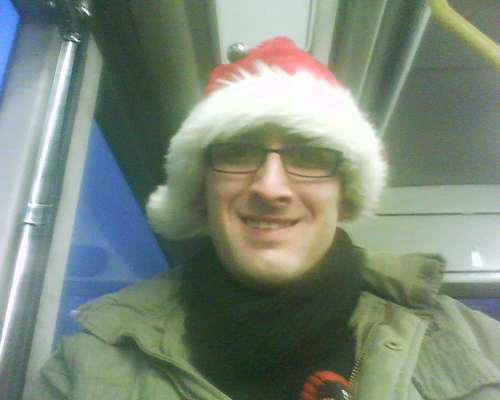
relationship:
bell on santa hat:
[226, 41, 249, 64] [144, 36, 388, 240]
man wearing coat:
[35, 36, 499, 399] [23, 245, 499, 399]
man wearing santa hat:
[35, 36, 499, 399] [144, 36, 388, 240]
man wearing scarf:
[35, 36, 499, 399] [178, 227, 366, 399]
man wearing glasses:
[35, 36, 499, 399] [204, 140, 346, 179]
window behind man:
[52, 117, 174, 355] [35, 36, 499, 399]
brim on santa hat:
[164, 61, 389, 226] [144, 36, 388, 240]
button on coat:
[383, 338, 402, 353] [23, 245, 499, 399]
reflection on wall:
[467, 243, 486, 272] [342, 182, 500, 297]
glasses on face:
[204, 140, 346, 179] [204, 126, 343, 293]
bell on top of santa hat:
[226, 41, 249, 64] [144, 36, 388, 240]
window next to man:
[52, 117, 174, 355] [35, 36, 499, 399]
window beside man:
[52, 117, 174, 355] [35, 36, 499, 399]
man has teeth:
[35, 36, 499, 399] [244, 217, 295, 230]